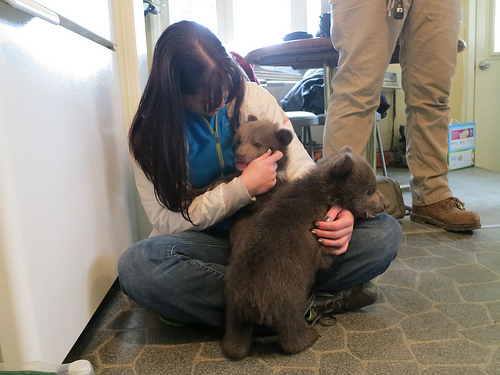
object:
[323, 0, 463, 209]
trousers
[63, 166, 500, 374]
floor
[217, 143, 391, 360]
bear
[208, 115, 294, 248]
bear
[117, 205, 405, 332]
jeans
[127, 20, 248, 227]
hair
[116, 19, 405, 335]
girl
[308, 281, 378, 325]
shoe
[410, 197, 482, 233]
boot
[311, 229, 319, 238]
fingernail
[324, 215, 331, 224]
fingernail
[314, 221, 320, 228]
fingernail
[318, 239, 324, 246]
fingernail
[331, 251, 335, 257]
fingernail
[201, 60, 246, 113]
bangs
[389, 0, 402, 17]
keys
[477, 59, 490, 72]
doorknob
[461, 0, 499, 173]
door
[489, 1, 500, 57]
window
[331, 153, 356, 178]
ear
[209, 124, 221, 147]
zipper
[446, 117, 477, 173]
box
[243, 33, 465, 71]
table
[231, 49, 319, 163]
chair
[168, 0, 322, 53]
window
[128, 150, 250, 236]
sleeve